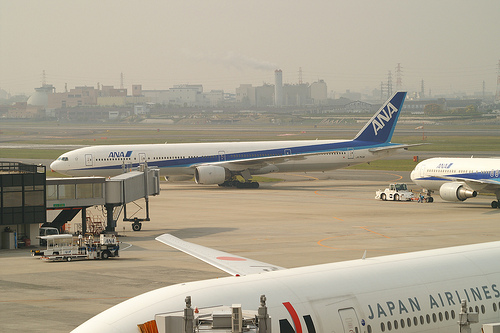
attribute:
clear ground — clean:
[252, 210, 294, 224]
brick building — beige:
[172, 82, 208, 109]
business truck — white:
[33, 214, 133, 261]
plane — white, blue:
[402, 143, 481, 208]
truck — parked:
[26, 220, 66, 250]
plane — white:
[376, 265, 401, 275]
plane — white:
[375, 272, 395, 286]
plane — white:
[316, 291, 334, 301]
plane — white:
[316, 275, 366, 325]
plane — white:
[218, 229, 460, 327]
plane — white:
[149, 242, 466, 327]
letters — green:
[363, 294, 421, 329]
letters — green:
[418, 286, 494, 316]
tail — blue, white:
[363, 93, 414, 147]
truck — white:
[374, 180, 411, 202]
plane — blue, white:
[66, 70, 387, 218]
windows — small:
[382, 300, 423, 330]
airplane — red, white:
[58, 202, 497, 330]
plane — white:
[94, 249, 496, 330]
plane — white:
[75, 254, 494, 324]